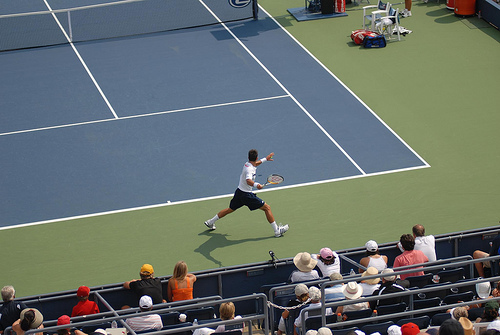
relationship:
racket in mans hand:
[262, 174, 284, 187] [257, 184, 263, 189]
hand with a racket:
[257, 184, 263, 189] [262, 174, 284, 187]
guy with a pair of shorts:
[204, 148, 291, 237] [228, 187, 265, 210]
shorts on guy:
[228, 187, 265, 210] [204, 148, 291, 237]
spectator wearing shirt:
[388, 230, 427, 282] [393, 249, 437, 272]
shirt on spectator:
[393, 249, 437, 272] [388, 230, 427, 282]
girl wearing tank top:
[163, 270, 205, 303] [166, 274, 204, 298]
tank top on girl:
[166, 274, 204, 298] [163, 270, 205, 303]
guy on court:
[204, 148, 291, 237] [0, 0, 500, 306]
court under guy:
[0, 0, 500, 306] [204, 148, 291, 237]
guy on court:
[204, 148, 291, 237] [3, 3, 498, 275]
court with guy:
[3, 3, 498, 275] [204, 148, 291, 237]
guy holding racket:
[204, 148, 291, 237] [255, 172, 282, 189]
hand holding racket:
[250, 177, 265, 191] [255, 172, 282, 189]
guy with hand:
[204, 148, 291, 237] [250, 177, 265, 191]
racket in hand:
[255, 172, 282, 189] [250, 177, 265, 191]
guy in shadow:
[204, 148, 291, 237] [196, 230, 277, 255]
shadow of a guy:
[196, 230, 277, 255] [204, 148, 291, 237]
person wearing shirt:
[70, 286, 100, 315] [72, 301, 99, 314]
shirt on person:
[72, 301, 99, 314] [70, 286, 100, 315]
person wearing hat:
[117, 262, 169, 310] [137, 260, 155, 282]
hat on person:
[137, 260, 155, 282] [117, 262, 169, 310]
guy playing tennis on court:
[202, 148, 288, 235] [0, 0, 433, 231]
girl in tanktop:
[167, 261, 197, 302] [170, 277, 190, 299]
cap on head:
[365, 240, 378, 258] [362, 237, 377, 254]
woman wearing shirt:
[389, 0, 437, 35] [394, 251, 427, 281]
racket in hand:
[262, 174, 284, 187] [257, 184, 263, 189]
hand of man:
[257, 184, 263, 189] [204, 149, 289, 238]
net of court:
[14, 7, 260, 45] [8, 8, 494, 333]